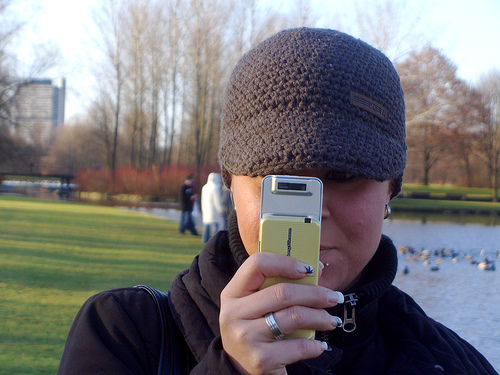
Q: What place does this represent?
A: It represents the park.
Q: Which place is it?
A: It is a park.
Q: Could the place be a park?
A: Yes, it is a park.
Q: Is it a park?
A: Yes, it is a park.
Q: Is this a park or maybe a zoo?
A: It is a park.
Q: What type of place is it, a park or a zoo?
A: It is a park.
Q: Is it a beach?
A: No, it is a park.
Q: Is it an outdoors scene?
A: Yes, it is outdoors.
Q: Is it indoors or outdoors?
A: It is outdoors.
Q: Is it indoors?
A: No, it is outdoors.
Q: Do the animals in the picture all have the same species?
A: Yes, all the animals are ducks.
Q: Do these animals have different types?
A: No, all the animals are ducks.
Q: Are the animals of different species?
A: No, all the animals are ducks.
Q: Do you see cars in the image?
A: No, there are no cars.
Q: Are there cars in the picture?
A: No, there are no cars.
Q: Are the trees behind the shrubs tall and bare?
A: Yes, the trees are tall and bare.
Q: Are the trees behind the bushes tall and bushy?
A: No, the trees are tall but bare.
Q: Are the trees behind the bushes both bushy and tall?
A: No, the trees are tall but bare.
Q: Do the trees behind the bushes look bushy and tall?
A: No, the trees are tall but bare.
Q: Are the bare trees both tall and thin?
A: Yes, the trees are tall and thin.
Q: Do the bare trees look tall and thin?
A: Yes, the trees are tall and thin.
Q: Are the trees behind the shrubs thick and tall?
A: No, the trees are tall but thin.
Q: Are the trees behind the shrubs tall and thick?
A: No, the trees are tall but thin.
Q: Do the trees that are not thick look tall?
A: Yes, the trees are tall.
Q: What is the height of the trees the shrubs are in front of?
A: The trees are tall.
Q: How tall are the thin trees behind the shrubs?
A: The trees are tall.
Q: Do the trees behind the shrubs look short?
A: No, the trees are tall.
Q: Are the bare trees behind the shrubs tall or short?
A: The trees are tall.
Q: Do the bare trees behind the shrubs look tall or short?
A: The trees are tall.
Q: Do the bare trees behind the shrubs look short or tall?
A: The trees are tall.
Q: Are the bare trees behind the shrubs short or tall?
A: The trees are tall.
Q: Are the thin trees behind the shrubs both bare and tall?
A: Yes, the trees are bare and tall.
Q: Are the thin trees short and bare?
A: No, the trees are bare but tall.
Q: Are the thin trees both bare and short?
A: No, the trees are bare but tall.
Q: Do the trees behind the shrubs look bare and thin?
A: Yes, the trees are bare and thin.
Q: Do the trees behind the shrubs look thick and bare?
A: No, the trees are bare but thin.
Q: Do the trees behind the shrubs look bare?
A: Yes, the trees are bare.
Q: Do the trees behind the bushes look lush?
A: No, the trees are bare.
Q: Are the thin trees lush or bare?
A: The trees are bare.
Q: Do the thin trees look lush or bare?
A: The trees are bare.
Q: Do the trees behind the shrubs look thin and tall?
A: Yes, the trees are thin and tall.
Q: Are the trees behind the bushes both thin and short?
A: No, the trees are thin but tall.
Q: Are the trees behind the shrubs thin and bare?
A: Yes, the trees are thin and bare.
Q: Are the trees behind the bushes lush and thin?
A: No, the trees are thin but bare.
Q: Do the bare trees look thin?
A: Yes, the trees are thin.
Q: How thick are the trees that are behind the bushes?
A: The trees are thin.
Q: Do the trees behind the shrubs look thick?
A: No, the trees are thin.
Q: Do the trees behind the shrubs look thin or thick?
A: The trees are thin.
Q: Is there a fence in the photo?
A: No, there are no fences.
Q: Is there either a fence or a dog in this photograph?
A: No, there are no fences or dogs.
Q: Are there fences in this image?
A: No, there are no fences.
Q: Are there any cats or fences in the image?
A: No, there are no fences or cats.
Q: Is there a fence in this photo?
A: No, there are no fences.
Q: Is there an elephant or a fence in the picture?
A: No, there are no fences or elephants.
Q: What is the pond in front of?
A: The pond is in front of the trees.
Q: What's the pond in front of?
A: The pond is in front of the trees.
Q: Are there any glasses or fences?
A: No, there are no fences or glasses.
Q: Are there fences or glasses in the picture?
A: No, there are no fences or glasses.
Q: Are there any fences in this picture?
A: No, there are no fences.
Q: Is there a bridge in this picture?
A: Yes, there is a bridge.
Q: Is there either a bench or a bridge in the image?
A: Yes, there is a bridge.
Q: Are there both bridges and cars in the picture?
A: No, there is a bridge but no cars.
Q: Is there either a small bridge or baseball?
A: Yes, there is a small bridge.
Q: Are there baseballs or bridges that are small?
A: Yes, the bridge is small.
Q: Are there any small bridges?
A: Yes, there is a small bridge.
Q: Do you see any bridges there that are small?
A: Yes, there is a bridge that is small.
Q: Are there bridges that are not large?
A: Yes, there is a small bridge.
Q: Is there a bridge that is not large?
A: Yes, there is a small bridge.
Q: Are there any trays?
A: No, there are no trays.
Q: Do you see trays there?
A: No, there are no trays.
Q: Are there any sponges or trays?
A: No, there are no trays or sponges.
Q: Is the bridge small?
A: Yes, the bridge is small.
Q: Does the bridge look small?
A: Yes, the bridge is small.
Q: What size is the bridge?
A: The bridge is small.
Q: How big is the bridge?
A: The bridge is small.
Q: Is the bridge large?
A: No, the bridge is small.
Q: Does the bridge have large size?
A: No, the bridge is small.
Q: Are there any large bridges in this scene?
A: No, there is a bridge but it is small.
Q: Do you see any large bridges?
A: No, there is a bridge but it is small.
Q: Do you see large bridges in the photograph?
A: No, there is a bridge but it is small.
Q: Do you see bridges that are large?
A: No, there is a bridge but it is small.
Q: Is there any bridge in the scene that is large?
A: No, there is a bridge but it is small.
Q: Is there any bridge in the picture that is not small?
A: No, there is a bridge but it is small.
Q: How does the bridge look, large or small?
A: The bridge is small.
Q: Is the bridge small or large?
A: The bridge is small.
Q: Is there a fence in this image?
A: No, there are no fences.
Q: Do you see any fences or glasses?
A: No, there are no fences or glasses.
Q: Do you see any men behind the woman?
A: Yes, there is a man behind the woman.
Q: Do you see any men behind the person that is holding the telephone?
A: Yes, there is a man behind the woman.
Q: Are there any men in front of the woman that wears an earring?
A: No, the man is behind the woman.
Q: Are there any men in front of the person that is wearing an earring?
A: No, the man is behind the woman.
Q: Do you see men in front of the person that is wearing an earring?
A: No, the man is behind the woman.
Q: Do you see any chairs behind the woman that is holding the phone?
A: No, there is a man behind the woman.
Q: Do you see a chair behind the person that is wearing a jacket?
A: No, there is a man behind the woman.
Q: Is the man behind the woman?
A: Yes, the man is behind the woman.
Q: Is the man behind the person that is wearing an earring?
A: Yes, the man is behind the woman.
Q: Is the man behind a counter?
A: No, the man is behind the woman.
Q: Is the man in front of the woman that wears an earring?
A: No, the man is behind the woman.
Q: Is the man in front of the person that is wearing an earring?
A: No, the man is behind the woman.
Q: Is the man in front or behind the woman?
A: The man is behind the woman.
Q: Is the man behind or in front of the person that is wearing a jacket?
A: The man is behind the woman.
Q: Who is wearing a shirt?
A: The man is wearing a shirt.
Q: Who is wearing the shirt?
A: The man is wearing a shirt.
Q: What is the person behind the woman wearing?
A: The man is wearing a shirt.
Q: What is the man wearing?
A: The man is wearing a shirt.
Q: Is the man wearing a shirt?
A: Yes, the man is wearing a shirt.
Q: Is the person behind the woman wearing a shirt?
A: Yes, the man is wearing a shirt.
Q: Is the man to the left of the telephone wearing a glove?
A: No, the man is wearing a shirt.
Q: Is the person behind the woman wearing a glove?
A: No, the man is wearing a shirt.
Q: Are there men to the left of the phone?
A: Yes, there is a man to the left of the phone.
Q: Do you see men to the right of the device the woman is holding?
A: No, the man is to the left of the telephone.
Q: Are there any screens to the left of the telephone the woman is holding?
A: No, there is a man to the left of the telephone.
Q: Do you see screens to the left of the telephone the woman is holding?
A: No, there is a man to the left of the telephone.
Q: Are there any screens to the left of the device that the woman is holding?
A: No, there is a man to the left of the telephone.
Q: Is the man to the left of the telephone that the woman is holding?
A: Yes, the man is to the left of the phone.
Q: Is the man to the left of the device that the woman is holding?
A: Yes, the man is to the left of the phone.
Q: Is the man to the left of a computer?
A: No, the man is to the left of the phone.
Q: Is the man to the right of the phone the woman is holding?
A: No, the man is to the left of the phone.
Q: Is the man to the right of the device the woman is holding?
A: No, the man is to the left of the phone.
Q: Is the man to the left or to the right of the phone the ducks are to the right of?
A: The man is to the left of the phone.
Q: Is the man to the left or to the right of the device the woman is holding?
A: The man is to the left of the phone.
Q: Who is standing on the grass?
A: The man is standing on the grass.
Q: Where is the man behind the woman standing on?
A: The man is standing on the grass.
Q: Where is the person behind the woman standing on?
A: The man is standing on the grass.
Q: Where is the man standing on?
A: The man is standing on the grass.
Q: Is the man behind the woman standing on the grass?
A: Yes, the man is standing on the grass.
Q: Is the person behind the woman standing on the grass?
A: Yes, the man is standing on the grass.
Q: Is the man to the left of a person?
A: Yes, the man is to the left of a person.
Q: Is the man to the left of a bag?
A: No, the man is to the left of a person.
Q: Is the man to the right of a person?
A: No, the man is to the left of a person.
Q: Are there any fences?
A: No, there are no fences.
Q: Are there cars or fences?
A: No, there are no fences or cars.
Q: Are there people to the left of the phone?
A: Yes, there is a person to the left of the phone.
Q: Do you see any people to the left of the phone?
A: Yes, there is a person to the left of the phone.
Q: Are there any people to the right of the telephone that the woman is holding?
A: No, the person is to the left of the telephone.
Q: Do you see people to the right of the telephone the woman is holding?
A: No, the person is to the left of the telephone.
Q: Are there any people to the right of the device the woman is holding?
A: No, the person is to the left of the telephone.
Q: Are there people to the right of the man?
A: Yes, there is a person to the right of the man.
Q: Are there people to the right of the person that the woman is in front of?
A: Yes, there is a person to the right of the man.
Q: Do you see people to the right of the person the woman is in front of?
A: Yes, there is a person to the right of the man.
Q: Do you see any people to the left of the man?
A: No, the person is to the right of the man.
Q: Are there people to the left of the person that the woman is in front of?
A: No, the person is to the right of the man.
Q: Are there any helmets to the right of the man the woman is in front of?
A: No, there is a person to the right of the man.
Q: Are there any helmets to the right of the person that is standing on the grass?
A: No, there is a person to the right of the man.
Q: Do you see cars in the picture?
A: No, there are no cars.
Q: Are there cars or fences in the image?
A: No, there are no cars or fences.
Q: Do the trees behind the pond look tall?
A: Yes, the trees are tall.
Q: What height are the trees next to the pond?
A: The trees are tall.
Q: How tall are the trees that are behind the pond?
A: The trees are tall.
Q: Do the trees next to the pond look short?
A: No, the trees are tall.